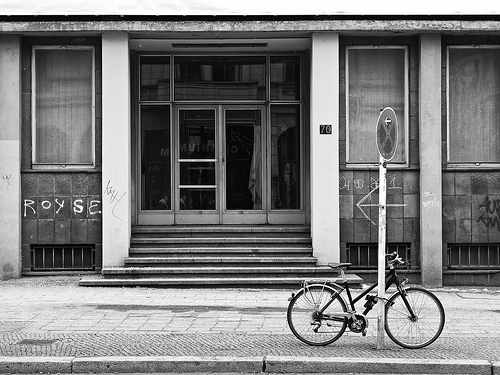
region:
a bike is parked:
[331, 194, 428, 361]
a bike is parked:
[321, 242, 401, 372]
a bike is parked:
[337, 250, 388, 341]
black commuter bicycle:
[279, 239, 450, 356]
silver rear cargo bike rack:
[290, 270, 347, 312]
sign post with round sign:
[360, 83, 411, 353]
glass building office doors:
[121, 28, 312, 229]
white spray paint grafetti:
[15, 183, 105, 223]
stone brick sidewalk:
[65, 331, 287, 353]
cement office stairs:
[146, 220, 296, 290]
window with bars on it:
[27, 240, 99, 272]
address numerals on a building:
[317, 114, 335, 144]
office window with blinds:
[29, 39, 101, 177]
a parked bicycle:
[282, 259, 447, 348]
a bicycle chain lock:
[369, 292, 391, 308]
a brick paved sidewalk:
[2, 267, 497, 360]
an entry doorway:
[171, 102, 222, 223]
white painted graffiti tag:
[17, 188, 98, 221]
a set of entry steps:
[81, 226, 352, 284]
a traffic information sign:
[373, 106, 398, 350]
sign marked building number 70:
[317, 120, 334, 136]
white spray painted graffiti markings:
[340, 174, 411, 226]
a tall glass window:
[33, 44, 95, 166]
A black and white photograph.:
[21, 37, 476, 362]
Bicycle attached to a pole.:
[280, 176, 470, 357]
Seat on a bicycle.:
[315, 253, 353, 278]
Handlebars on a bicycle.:
[377, 243, 403, 283]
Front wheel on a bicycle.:
[380, 281, 451, 351]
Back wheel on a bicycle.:
[285, 268, 350, 344]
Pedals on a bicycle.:
[337, 300, 372, 345]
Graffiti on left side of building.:
[15, 176, 105, 231]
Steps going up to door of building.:
[112, 210, 358, 295]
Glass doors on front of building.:
[128, 87, 305, 232]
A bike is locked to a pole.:
[280, 223, 457, 343]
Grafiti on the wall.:
[15, 180, 105, 235]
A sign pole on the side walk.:
[365, 153, 397, 355]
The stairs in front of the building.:
[80, 206, 360, 288]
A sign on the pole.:
[360, 98, 406, 163]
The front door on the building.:
[135, 95, 310, 225]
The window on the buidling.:
[25, 37, 97, 177]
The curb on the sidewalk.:
[0, 350, 499, 371]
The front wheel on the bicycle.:
[383, 283, 444, 349]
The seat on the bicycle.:
[323, 249, 353, 274]